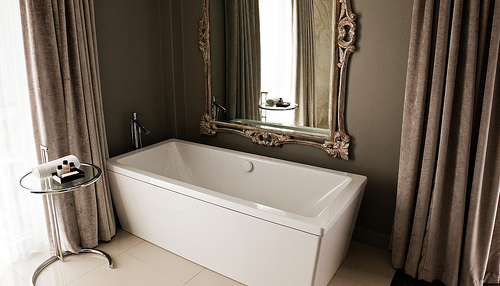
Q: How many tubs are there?
A: One.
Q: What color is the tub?
A: White.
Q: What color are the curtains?
A: Brown.